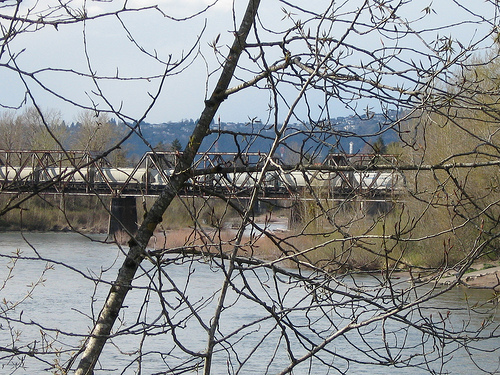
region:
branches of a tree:
[66, 21, 494, 352]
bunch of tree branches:
[117, 49, 488, 261]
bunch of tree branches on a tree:
[180, 16, 495, 346]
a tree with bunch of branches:
[30, 3, 291, 373]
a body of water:
[29, 269, 86, 309]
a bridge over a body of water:
[6, 138, 497, 262]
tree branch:
[202, 38, 313, 110]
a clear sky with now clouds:
[105, 42, 133, 69]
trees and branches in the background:
[22, 95, 466, 199]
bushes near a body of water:
[160, 185, 492, 299]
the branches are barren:
[170, 194, 340, 369]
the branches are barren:
[234, 239, 410, 364]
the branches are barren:
[145, 287, 309, 358]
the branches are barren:
[192, 309, 296, 363]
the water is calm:
[347, 322, 402, 368]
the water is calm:
[35, 283, 85, 313]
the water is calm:
[21, 275, 91, 332]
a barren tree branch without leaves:
[220, 225, 398, 350]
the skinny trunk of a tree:
[100, 215, 160, 305]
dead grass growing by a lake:
[350, 201, 420, 258]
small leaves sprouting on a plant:
[5, 273, 46, 344]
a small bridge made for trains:
[65, 145, 193, 242]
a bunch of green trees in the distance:
[111, 102, 173, 163]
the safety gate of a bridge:
[12, 139, 119, 193]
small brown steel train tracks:
[108, 173, 146, 207]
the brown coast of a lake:
[444, 255, 498, 309]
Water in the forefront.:
[1, 210, 496, 372]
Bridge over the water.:
[0, 144, 421, 199]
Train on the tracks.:
[0, 159, 417, 195]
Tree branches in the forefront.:
[5, 1, 497, 371]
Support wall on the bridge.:
[102, 92, 140, 194]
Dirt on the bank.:
[431, 255, 498, 292]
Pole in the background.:
[345, 140, 355, 157]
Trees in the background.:
[62, 98, 407, 153]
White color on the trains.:
[0, 159, 403, 194]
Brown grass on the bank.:
[157, 226, 275, 256]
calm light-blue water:
[0, 227, 491, 367]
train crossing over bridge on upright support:
[0, 150, 400, 235]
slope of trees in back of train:
[5, 120, 400, 160]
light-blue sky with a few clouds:
[5, 1, 490, 122]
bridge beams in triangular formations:
[10, 155, 365, 195]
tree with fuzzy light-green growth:
[311, 50, 491, 270]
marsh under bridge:
[5, 195, 215, 230]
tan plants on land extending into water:
[120, 225, 270, 260]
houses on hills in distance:
[122, 122, 205, 152]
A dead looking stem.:
[225, 323, 252, 346]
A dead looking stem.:
[318, 348, 360, 370]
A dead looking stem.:
[381, 326, 411, 333]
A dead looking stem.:
[377, 340, 416, 350]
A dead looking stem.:
[272, 215, 322, 255]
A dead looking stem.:
[294, 205, 349, 233]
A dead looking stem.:
[356, 77, 383, 94]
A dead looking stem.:
[377, 47, 405, 69]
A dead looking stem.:
[391, 21, 406, 46]